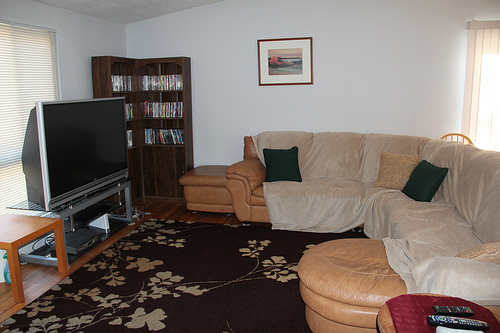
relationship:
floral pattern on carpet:
[59, 272, 107, 302] [0, 217, 374, 332]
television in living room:
[20, 96, 129, 212] [2, 5, 497, 331]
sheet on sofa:
[374, 194, 496, 248] [180, 94, 471, 330]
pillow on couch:
[400, 158, 448, 203] [223, 130, 499, 332]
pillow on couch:
[262, 145, 302, 183] [223, 130, 499, 332]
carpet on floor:
[0, 217, 374, 332] [3, 192, 366, 330]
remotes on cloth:
[431, 307, 487, 329] [387, 290, 499, 330]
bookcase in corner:
[137, 56, 193, 197] [111, 9, 137, 73]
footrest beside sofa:
[176, 156, 245, 223] [182, 162, 262, 217]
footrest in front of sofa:
[297, 224, 421, 330] [217, 112, 495, 329]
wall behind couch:
[127, 3, 462, 200] [240, 119, 497, 331]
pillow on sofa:
[402, 158, 445, 203] [217, 112, 495, 329]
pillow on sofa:
[261, 145, 302, 183] [217, 112, 495, 329]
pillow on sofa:
[374, 150, 423, 192] [217, 112, 495, 329]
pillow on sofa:
[455, 241, 497, 262] [217, 112, 495, 329]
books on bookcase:
[139, 72, 186, 145] [91, 55, 145, 205]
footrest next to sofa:
[178, 164, 235, 216] [227, 127, 498, 258]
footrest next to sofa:
[297, 238, 421, 332] [227, 127, 498, 258]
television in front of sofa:
[20, 96, 129, 212] [217, 112, 495, 329]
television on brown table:
[20, 95, 129, 211] [0, 213, 67, 305]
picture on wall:
[256, 35, 316, 87] [198, 33, 440, 127]